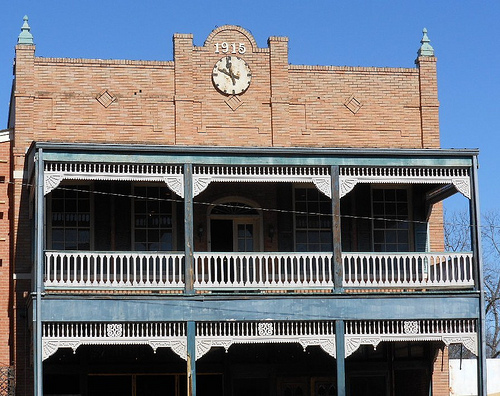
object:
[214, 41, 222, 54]
number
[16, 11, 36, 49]
finial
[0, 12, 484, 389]
building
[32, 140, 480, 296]
balcony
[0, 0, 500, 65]
sky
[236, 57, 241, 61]
numbers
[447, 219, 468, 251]
branches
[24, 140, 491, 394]
house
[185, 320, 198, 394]
board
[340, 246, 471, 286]
railing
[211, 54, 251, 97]
clock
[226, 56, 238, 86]
hands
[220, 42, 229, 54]
numbers